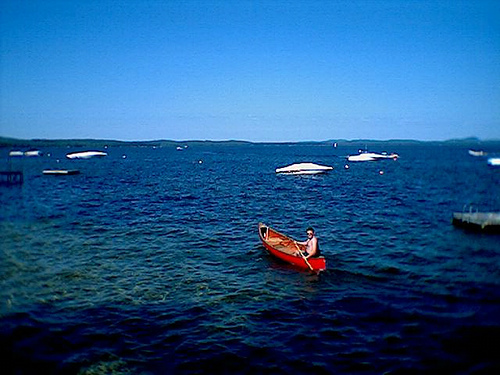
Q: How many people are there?
A: One.